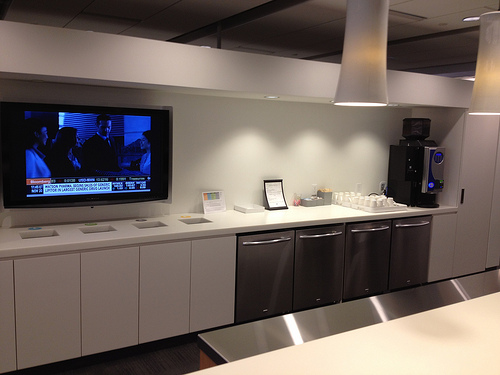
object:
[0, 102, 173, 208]
border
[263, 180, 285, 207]
paper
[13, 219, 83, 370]
counter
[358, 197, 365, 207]
cups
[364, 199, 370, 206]
white cups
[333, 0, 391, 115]
lamp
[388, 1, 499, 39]
ceiling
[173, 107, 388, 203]
wall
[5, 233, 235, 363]
cabinets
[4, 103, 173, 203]
television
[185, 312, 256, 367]
edge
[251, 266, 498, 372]
tabletop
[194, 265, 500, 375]
steel counter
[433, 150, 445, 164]
blue lights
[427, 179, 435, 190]
blue lights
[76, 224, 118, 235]
holes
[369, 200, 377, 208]
cups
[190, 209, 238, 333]
counter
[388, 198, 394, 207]
cups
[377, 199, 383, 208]
cups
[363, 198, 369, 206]
cups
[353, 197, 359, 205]
cups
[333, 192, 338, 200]
cups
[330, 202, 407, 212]
tray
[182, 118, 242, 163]
wall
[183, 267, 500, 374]
kitchen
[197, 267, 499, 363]
counter top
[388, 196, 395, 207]
cups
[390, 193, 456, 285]
counter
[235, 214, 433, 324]
cabinets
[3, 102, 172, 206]
tv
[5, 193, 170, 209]
bottom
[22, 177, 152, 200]
information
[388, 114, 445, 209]
machine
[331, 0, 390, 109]
light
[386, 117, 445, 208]
beverage dispenser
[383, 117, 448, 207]
beverage machine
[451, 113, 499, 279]
door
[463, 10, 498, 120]
light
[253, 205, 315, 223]
countertop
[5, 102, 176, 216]
tv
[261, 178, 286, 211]
frame